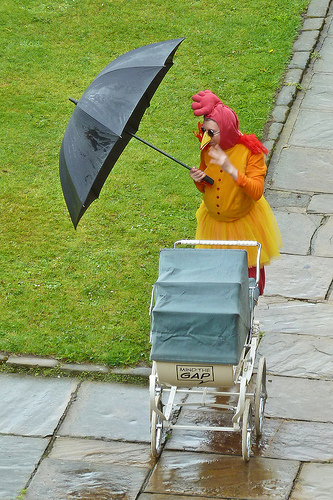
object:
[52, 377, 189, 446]
square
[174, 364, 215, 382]
sign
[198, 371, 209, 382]
letters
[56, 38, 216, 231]
umbrella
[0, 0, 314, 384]
grass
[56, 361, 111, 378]
bricks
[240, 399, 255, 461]
wheel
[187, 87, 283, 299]
woman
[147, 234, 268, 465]
carriage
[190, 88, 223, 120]
comb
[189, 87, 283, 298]
costume